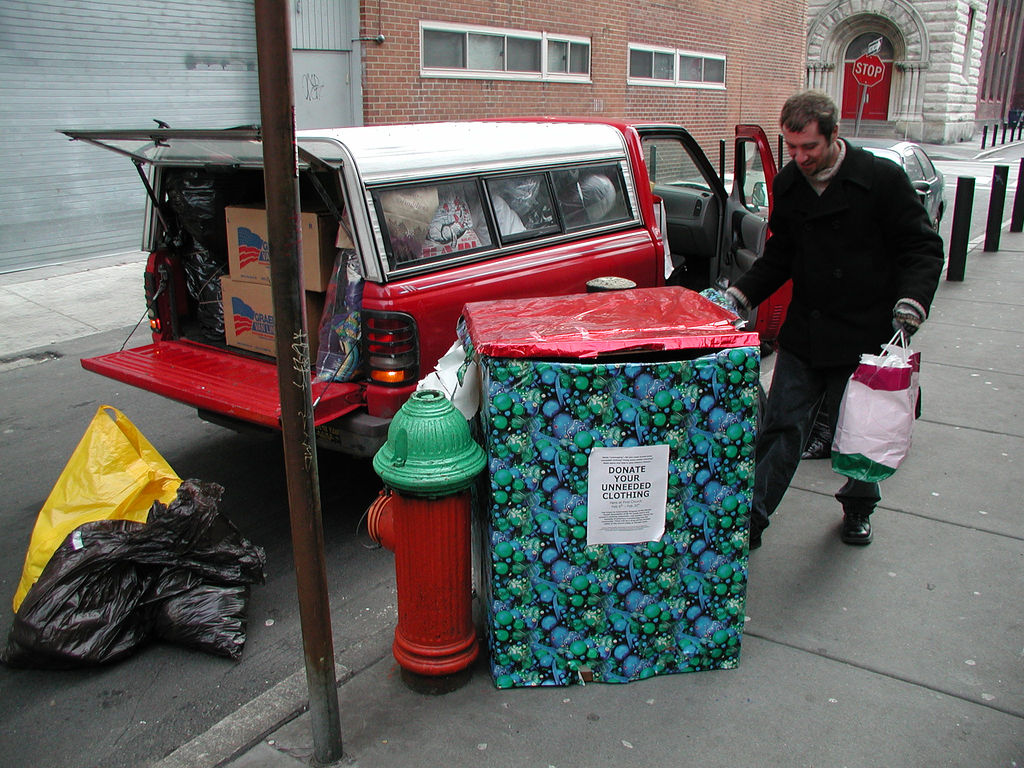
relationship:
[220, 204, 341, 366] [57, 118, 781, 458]
boxes are in truck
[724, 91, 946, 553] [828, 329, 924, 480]
man holding bag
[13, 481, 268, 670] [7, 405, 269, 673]
bags are in a pile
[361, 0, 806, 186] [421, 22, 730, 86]
building has windows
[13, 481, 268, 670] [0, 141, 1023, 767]
bags are on street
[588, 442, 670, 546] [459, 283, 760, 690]
paper on box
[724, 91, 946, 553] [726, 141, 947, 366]
man wearing a coat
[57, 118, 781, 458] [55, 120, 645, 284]
truck has a camper shell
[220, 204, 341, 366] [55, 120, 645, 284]
boxes are in camper shell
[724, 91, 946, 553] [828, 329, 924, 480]
man carrying a bag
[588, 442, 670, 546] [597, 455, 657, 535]
paper has black lettering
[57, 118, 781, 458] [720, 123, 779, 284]
truck has a door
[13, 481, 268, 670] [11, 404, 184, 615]
bags are near bag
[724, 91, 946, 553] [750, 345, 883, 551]
man wearing pants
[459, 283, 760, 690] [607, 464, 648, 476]
box for donating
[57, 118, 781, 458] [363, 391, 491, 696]
truck near hydrant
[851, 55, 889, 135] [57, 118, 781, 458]
sign behind truck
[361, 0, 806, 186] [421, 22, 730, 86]
building has several windows